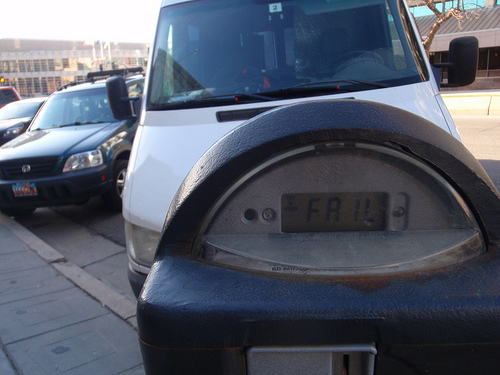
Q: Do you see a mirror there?
A: Yes, there is a mirror.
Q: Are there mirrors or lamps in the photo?
A: Yes, there is a mirror.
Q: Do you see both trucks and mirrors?
A: Yes, there are both a mirror and a truck.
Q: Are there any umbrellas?
A: No, there are no umbrellas.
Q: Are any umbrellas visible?
A: No, there are no umbrellas.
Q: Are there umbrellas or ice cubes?
A: No, there are no umbrellas or ice cubes.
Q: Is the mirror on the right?
A: Yes, the mirror is on the right of the image.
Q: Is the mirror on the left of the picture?
A: No, the mirror is on the right of the image.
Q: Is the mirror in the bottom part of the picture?
A: No, the mirror is in the top of the image.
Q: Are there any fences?
A: No, there are no fences.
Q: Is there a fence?
A: No, there are no fences.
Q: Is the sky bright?
A: Yes, the sky is bright.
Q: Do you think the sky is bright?
A: Yes, the sky is bright.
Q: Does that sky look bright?
A: Yes, the sky is bright.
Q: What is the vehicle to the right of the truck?
A: The vehicle is a van.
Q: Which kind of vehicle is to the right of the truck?
A: The vehicle is a van.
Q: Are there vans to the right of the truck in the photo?
A: Yes, there is a van to the right of the truck.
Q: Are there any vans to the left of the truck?
A: No, the van is to the right of the truck.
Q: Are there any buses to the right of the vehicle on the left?
A: No, there is a van to the right of the truck.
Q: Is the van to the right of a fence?
A: No, the van is to the right of the truck.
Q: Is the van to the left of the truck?
A: No, the van is to the right of the truck.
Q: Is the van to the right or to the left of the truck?
A: The van is to the right of the truck.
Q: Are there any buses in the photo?
A: No, there are no buses.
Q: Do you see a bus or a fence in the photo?
A: No, there are no buses or fences.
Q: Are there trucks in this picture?
A: Yes, there is a truck.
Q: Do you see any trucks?
A: Yes, there is a truck.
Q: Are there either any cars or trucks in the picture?
A: Yes, there is a truck.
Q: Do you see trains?
A: No, there are no trains.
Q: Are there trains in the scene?
A: No, there are no trains.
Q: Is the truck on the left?
A: Yes, the truck is on the left of the image.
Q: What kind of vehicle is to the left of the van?
A: The vehicle is a truck.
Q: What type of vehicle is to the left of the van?
A: The vehicle is a truck.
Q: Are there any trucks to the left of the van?
A: Yes, there is a truck to the left of the van.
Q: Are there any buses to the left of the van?
A: No, there is a truck to the left of the van.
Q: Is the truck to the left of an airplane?
A: No, the truck is to the left of the van.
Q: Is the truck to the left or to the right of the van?
A: The truck is to the left of the van.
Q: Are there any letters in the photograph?
A: Yes, there are letters.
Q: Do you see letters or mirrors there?
A: Yes, there are letters.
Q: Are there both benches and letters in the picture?
A: No, there are letters but no benches.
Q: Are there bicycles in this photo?
A: No, there are no bicycles.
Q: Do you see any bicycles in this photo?
A: No, there are no bicycles.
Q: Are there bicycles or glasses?
A: No, there are no bicycles or glasses.